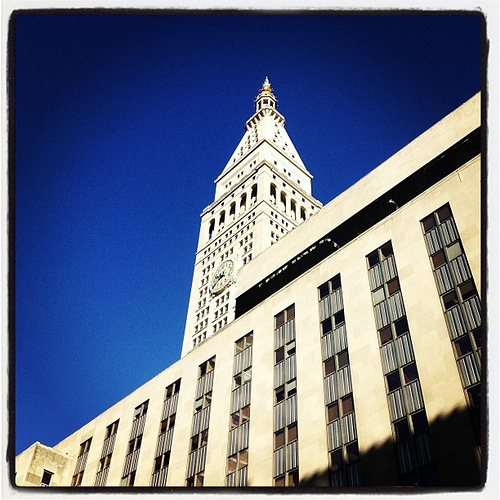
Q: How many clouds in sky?
A: 0.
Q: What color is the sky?
A: Blue.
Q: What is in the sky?
A: Nothing.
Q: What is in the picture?
A: Buildings.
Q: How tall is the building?
A: Tall.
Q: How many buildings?
A: 2.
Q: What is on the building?
A: Clock.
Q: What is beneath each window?
A: Squares.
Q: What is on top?
A: Platform.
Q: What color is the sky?
A: Blue.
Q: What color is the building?
A: White.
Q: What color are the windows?
A: Gray.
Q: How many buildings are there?
A: One.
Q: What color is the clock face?
A: White.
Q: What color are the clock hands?
A: Black.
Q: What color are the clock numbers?
A: Black.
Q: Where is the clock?
A: On the building.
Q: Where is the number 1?
A: On the clock.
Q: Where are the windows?
A: On the building.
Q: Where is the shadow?
A: On the building.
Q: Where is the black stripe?
A: Near the top of the building.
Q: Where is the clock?
A: On the tower.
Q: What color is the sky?
A: Deep blue.